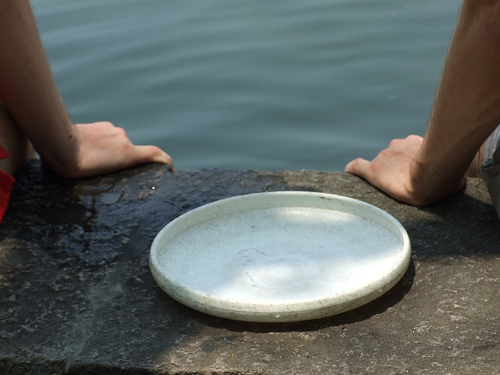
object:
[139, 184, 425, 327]
frisbee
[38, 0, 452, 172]
water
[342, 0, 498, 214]
person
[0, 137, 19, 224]
shorts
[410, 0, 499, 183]
arm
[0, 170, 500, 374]
wall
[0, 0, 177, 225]
man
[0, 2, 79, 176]
arm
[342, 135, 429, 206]
hand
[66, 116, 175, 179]
hand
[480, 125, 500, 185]
swimming trunks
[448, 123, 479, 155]
vein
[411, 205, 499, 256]
shadow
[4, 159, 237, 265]
wet spot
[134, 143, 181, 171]
pinky finger